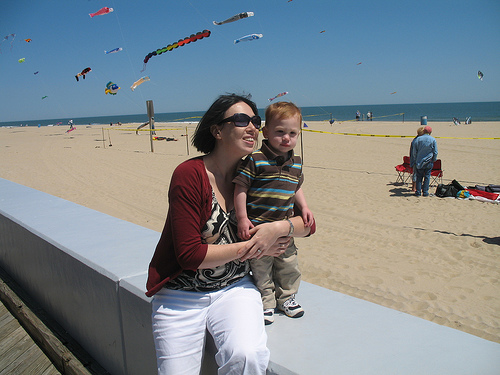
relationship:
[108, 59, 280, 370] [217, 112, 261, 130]
lady wearing sunglasses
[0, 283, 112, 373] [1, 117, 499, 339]
boardwalk along beach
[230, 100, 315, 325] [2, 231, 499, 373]
child on wall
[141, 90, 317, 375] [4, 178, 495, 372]
lady on wall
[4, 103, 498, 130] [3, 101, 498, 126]
water in ocean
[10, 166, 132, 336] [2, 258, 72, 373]
wall along boardwalk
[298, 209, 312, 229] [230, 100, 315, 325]
hand of child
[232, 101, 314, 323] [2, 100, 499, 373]
child at beach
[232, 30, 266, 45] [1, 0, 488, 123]
kite in sky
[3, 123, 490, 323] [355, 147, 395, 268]
sand at beach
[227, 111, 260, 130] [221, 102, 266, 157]
sunglasses on face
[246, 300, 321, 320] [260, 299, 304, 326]
shoes on feet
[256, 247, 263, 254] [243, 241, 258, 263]
ring on finger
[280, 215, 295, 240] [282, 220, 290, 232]
object on wrist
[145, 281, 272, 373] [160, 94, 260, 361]
pants on woman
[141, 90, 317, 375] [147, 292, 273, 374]
lady wearing pants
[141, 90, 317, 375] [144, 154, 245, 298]
lady wearing brown sweater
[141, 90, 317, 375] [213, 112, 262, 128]
lady wearing sunglasses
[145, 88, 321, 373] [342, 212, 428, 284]
people standing in sand